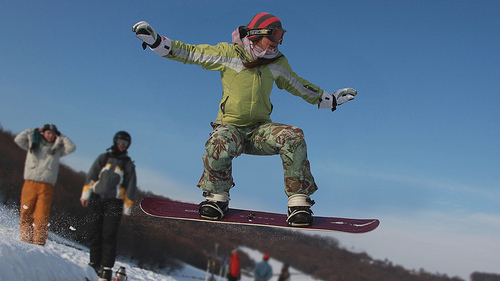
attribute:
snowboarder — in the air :
[119, 4, 429, 273]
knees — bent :
[179, 122, 319, 173]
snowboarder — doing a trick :
[123, 17, 398, 259]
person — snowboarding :
[116, 9, 404, 269]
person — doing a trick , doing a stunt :
[107, 7, 436, 262]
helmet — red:
[239, 10, 291, 43]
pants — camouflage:
[186, 118, 314, 198]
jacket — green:
[178, 39, 333, 134]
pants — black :
[75, 187, 132, 272]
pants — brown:
[11, 172, 50, 251]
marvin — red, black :
[241, 3, 277, 43]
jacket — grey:
[15, 129, 73, 184]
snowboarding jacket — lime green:
[152, 33, 338, 126]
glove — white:
[130, 18, 163, 49]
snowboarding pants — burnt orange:
[15, 179, 57, 249]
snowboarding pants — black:
[82, 189, 123, 272]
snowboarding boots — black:
[193, 189, 233, 218]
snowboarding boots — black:
[281, 199, 320, 226]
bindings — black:
[196, 199, 225, 214]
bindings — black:
[283, 207, 312, 221]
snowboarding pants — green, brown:
[197, 117, 322, 204]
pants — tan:
[17, 178, 58, 248]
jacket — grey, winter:
[11, 125, 78, 183]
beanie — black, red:
[244, 10, 285, 35]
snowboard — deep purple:
[137, 193, 382, 241]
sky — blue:
[8, 9, 96, 76]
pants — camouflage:
[195, 119, 319, 197]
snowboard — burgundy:
[137, 193, 380, 233]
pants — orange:
[18, 177, 51, 247]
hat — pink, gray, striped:
[249, 9, 281, 36]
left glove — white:
[318, 86, 358, 112]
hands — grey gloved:
[125, 15, 355, 118]